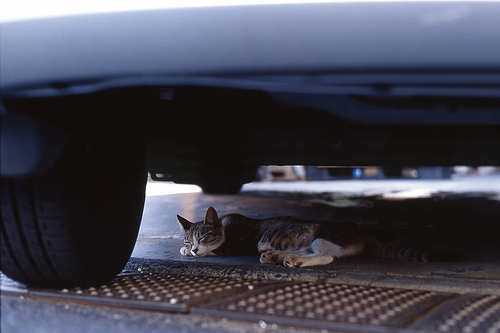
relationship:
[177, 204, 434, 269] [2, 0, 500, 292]
cat under car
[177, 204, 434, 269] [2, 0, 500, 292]
cat sleeping under car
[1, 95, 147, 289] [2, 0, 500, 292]
tire under car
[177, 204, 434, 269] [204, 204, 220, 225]
cat has an ear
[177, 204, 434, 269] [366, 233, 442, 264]
cat has a tail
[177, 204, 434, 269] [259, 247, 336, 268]
cat has feet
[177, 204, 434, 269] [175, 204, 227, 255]
cat has a head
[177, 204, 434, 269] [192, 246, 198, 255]
cat has a nose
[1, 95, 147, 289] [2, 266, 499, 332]
tire on steel grate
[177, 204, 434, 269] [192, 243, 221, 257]
cat has white beard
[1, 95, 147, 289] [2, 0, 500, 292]
tire in rear of car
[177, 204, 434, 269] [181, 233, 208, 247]
cat has eyes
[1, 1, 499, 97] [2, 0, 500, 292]
bumper in rear car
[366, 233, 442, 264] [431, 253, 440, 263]
tail has black tip